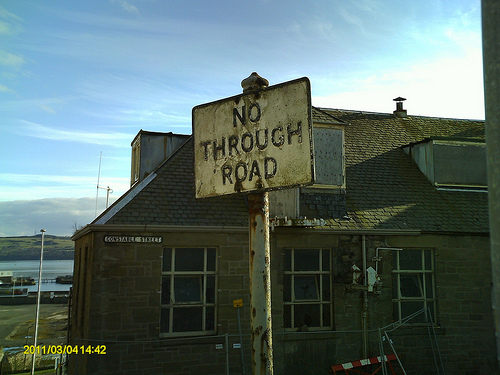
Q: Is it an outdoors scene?
A: Yes, it is outdoors.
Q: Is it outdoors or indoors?
A: It is outdoors.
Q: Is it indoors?
A: No, it is outdoors.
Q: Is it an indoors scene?
A: No, it is outdoors.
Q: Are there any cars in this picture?
A: No, there are no cars.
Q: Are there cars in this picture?
A: No, there are no cars.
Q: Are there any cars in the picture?
A: No, there are no cars.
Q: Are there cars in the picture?
A: No, there are no cars.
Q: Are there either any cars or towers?
A: No, there are no cars or towers.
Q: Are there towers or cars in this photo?
A: No, there are no cars or towers.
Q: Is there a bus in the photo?
A: No, there are no buses.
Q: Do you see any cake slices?
A: No, there are no cake slices.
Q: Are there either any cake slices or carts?
A: No, there are no cake slices or carts.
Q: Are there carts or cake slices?
A: No, there are no cake slices or carts.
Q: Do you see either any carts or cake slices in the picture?
A: No, there are no cake slices or carts.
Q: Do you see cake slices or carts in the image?
A: No, there are no cake slices or carts.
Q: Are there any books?
A: No, there are no books.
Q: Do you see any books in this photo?
A: No, there are no books.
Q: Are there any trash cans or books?
A: No, there are no books or trash cans.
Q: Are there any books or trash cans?
A: No, there are no books or trash cans.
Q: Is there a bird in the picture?
A: No, there are no birds.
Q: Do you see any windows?
A: Yes, there is a window.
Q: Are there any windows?
A: Yes, there is a window.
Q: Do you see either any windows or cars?
A: Yes, there is a window.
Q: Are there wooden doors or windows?
A: Yes, there is a wood window.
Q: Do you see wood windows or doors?
A: Yes, there is a wood window.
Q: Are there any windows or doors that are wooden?
A: Yes, the window is wooden.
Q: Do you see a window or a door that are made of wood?
A: Yes, the window is made of wood.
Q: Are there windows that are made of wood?
A: Yes, there is a window that is made of wood.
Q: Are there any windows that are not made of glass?
A: Yes, there is a window that is made of wood.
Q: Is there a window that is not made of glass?
A: Yes, there is a window that is made of wood.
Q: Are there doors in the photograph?
A: No, there are no doors.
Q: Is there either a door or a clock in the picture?
A: No, there are no doors or clocks.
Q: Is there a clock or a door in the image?
A: No, there are no doors or clocks.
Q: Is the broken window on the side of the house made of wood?
A: Yes, the window is made of wood.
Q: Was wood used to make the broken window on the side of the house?
A: Yes, the window is made of wood.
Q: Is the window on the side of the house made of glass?
A: No, the window is made of wood.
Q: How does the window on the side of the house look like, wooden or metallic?
A: The window is wooden.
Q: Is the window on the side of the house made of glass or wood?
A: The window is made of wood.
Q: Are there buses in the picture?
A: No, there are no buses.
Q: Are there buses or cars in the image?
A: No, there are no buses or cars.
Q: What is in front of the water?
A: The house is in front of the water.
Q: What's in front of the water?
A: The house is in front of the water.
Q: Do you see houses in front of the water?
A: Yes, there is a house in front of the water.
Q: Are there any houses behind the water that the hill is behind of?
A: No, the house is in front of the water.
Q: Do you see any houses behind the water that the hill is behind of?
A: No, the house is in front of the water.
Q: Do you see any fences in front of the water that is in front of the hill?
A: No, there is a house in front of the water.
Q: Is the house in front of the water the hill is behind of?
A: Yes, the house is in front of the water.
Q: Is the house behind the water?
A: No, the house is in front of the water.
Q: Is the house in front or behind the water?
A: The house is in front of the water.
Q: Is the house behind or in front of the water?
A: The house is in front of the water.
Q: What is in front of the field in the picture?
A: The house is in front of the field.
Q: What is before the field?
A: The house is in front of the field.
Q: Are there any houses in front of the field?
A: Yes, there is a house in front of the field.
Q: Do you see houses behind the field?
A: No, the house is in front of the field.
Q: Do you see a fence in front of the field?
A: No, there is a house in front of the field.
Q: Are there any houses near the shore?
A: Yes, there is a house near the shore.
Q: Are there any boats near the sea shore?
A: No, there is a house near the sea shore.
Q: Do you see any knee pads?
A: No, there are no knee pads.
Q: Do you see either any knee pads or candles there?
A: No, there are no knee pads or candles.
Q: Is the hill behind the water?
A: Yes, the hill is behind the water.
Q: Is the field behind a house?
A: Yes, the field is behind a house.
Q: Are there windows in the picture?
A: Yes, there is a window.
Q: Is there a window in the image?
A: Yes, there is a window.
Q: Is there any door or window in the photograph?
A: Yes, there is a window.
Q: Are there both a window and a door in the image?
A: No, there is a window but no doors.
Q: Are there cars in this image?
A: No, there are no cars.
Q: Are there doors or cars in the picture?
A: No, there are no cars or doors.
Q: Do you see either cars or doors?
A: No, there are no cars or doors.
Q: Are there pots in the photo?
A: No, there are no pots.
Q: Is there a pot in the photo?
A: No, there are no pots.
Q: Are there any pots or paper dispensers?
A: No, there are no pots or paper dispensers.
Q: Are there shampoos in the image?
A: No, there are no shampoos.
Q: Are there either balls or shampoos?
A: No, there are no shampoos or balls.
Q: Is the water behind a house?
A: Yes, the water is behind a house.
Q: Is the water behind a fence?
A: No, the water is behind a house.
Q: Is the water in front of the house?
A: No, the water is behind the house.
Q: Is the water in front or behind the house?
A: The water is behind the house.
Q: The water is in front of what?
A: The water is in front of the hill.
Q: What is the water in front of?
A: The water is in front of the hill.